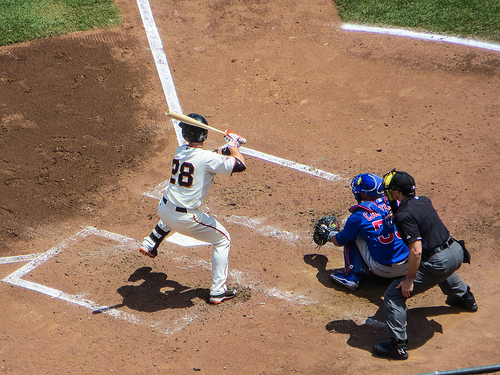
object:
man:
[136, 113, 245, 305]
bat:
[165, 109, 247, 145]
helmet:
[178, 113, 208, 143]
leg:
[138, 217, 172, 258]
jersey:
[162, 145, 233, 210]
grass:
[0, 0, 124, 46]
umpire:
[372, 167, 477, 360]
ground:
[0, 0, 494, 369]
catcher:
[313, 173, 416, 290]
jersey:
[336, 196, 409, 265]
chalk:
[3, 220, 243, 342]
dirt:
[1, 0, 500, 375]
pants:
[383, 237, 469, 341]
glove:
[313, 216, 341, 246]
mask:
[382, 171, 395, 214]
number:
[178, 162, 195, 188]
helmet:
[350, 173, 385, 198]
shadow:
[91, 266, 214, 315]